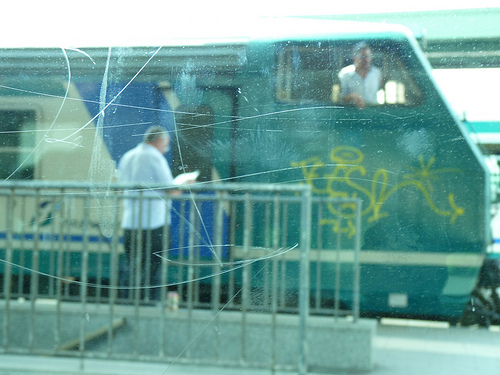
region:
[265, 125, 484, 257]
yellow graffiti on a train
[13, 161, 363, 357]
tall metal fences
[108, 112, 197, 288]
older man in white shirt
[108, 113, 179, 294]
man wearing black pants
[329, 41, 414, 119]
train driver wearing white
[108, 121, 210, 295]
person waiting for train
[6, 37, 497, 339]
a light green train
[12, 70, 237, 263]
blue and white siding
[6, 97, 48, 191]
a train window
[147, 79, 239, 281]
a blue and green train door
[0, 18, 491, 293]
this is a train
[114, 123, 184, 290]
this is a man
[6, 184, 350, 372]
metal grills are behind the man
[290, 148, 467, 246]
the train is caligraphed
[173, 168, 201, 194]
the man is holding a paper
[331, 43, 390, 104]
the man is looking outside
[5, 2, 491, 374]
the photo is not clear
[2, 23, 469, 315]
the train is yellow in color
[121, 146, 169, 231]
the man is wearing a white shirt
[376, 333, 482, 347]
a white strip is drawn on the path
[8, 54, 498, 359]
the photo is clear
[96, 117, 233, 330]
a man is in the photo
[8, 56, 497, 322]
a train is in the photo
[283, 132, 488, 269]
graffiti is on the train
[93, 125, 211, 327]
the man is wearing clothes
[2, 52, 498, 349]
the photo was taken outside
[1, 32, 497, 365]
the photo was taken outdoors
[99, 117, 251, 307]
the man is reading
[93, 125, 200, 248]
the man has a white top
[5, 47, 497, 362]
the photo was taken during the day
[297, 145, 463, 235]
Large scribbled yellow graffiti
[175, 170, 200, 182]
White newspaper in hand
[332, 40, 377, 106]
Man in white shirt on train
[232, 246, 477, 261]
Long painted white stripe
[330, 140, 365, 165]
Yellow scribbled circle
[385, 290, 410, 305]
Small white square on train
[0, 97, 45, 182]
Window in side of train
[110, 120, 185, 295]
Man in white shirt waiting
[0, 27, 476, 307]
Long green train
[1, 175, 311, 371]
Metal pole fence